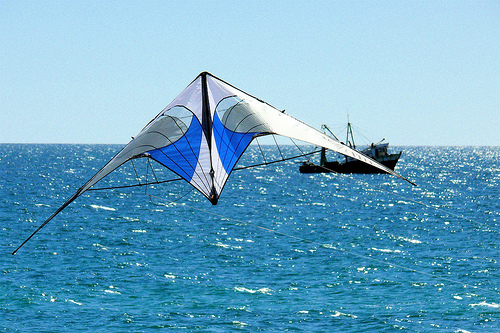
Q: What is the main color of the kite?
A: White.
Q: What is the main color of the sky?
A: Blue.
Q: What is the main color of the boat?
A: Black.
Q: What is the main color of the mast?
A: Black.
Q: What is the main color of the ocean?
A: Blue.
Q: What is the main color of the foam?
A: White.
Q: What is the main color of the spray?
A: White.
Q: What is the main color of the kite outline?
A: Black.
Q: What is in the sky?
A: A kite.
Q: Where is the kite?
A: In the sky.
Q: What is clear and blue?
A: The sky.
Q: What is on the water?
A: The boat.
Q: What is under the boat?
A: The water.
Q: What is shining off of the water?
A: The sunlight.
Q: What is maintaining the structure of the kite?
A: The frame.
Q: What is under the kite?
A: The ocean.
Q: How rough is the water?
A: The water is calm.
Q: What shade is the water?
A: Blue.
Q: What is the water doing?
A: Sparkling.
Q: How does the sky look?
A: Clear.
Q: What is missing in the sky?
A: Clouds.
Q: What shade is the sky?
A: Light blue.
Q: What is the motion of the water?
A: Tranquil.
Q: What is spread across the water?
A: Ripples.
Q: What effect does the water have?
A: Soothing.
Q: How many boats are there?
A: 1.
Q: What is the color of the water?
A: Blue.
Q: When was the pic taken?
A: During the day.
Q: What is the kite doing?
A: Flying.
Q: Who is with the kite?
A: No one.